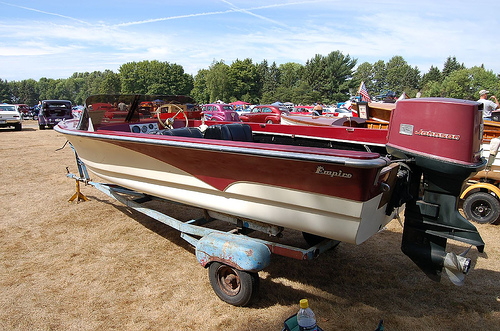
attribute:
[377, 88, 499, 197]
engine — red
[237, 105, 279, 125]
car — red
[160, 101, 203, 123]
car — red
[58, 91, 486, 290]
boat — red, white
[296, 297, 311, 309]
top — yellow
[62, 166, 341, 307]
boat trailer — rusty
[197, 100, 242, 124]
car — purple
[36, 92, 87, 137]
car — vintage, black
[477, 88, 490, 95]
cap — beige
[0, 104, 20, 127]
car — white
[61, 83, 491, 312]
boat — red, white, Empico brand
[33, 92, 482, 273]
boat trailer — old, red, blue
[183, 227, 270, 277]
mudgear — blue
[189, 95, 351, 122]
cars — classics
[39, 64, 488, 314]
boat — red, white, long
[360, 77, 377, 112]
flag — American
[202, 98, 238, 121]
car — pink, vintage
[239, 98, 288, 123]
car — red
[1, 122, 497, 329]
grass — dry, parched